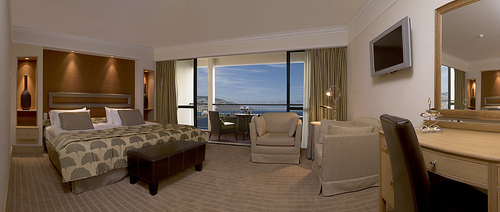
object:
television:
[367, 15, 415, 78]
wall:
[347, 4, 435, 131]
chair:
[247, 111, 304, 165]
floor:
[10, 131, 381, 211]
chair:
[382, 116, 440, 211]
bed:
[42, 102, 209, 195]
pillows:
[57, 111, 96, 132]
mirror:
[434, 2, 499, 119]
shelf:
[18, 110, 38, 126]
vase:
[21, 73, 33, 110]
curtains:
[155, 61, 177, 123]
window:
[176, 52, 314, 144]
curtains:
[308, 47, 348, 163]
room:
[0, 0, 499, 211]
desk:
[373, 115, 499, 211]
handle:
[429, 158, 438, 167]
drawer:
[422, 149, 490, 190]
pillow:
[255, 116, 268, 136]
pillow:
[287, 115, 298, 138]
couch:
[311, 119, 381, 196]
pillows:
[322, 123, 371, 146]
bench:
[126, 140, 212, 195]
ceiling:
[4, 2, 435, 61]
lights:
[106, 50, 115, 57]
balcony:
[198, 99, 304, 145]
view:
[195, 61, 304, 132]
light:
[18, 56, 31, 64]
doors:
[176, 53, 306, 146]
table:
[236, 111, 255, 135]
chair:
[207, 110, 234, 143]